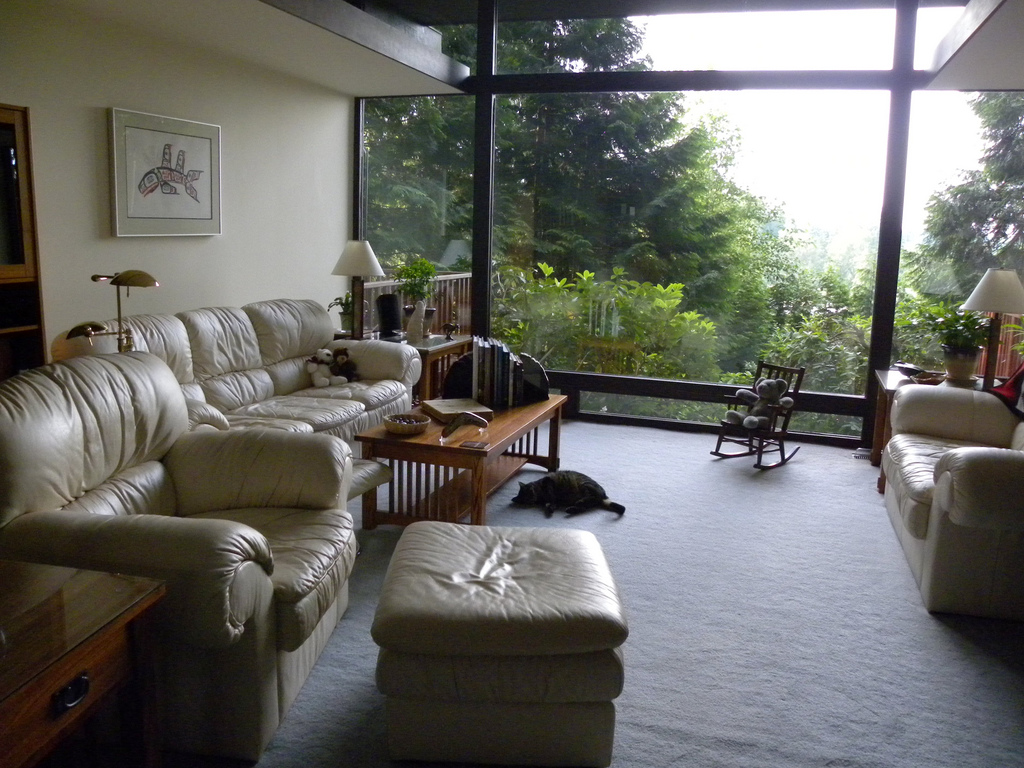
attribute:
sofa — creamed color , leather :
[93, 289, 426, 461]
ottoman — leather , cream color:
[363, 517, 627, 751]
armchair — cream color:
[8, 350, 373, 762]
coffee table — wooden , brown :
[372, 356, 569, 533]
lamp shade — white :
[324, 239, 385, 287]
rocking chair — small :
[720, 361, 796, 475]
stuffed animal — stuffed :
[731, 380, 788, 439]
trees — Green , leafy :
[461, 25, 993, 380]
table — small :
[861, 348, 1007, 412]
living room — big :
[97, 0, 979, 751]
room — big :
[45, 11, 1011, 752]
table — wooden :
[355, 372, 580, 527]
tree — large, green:
[549, 108, 755, 270]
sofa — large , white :
[58, 294, 428, 479]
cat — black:
[503, 449, 627, 527]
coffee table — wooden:
[357, 380, 566, 529]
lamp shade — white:
[329, 237, 384, 339]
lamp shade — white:
[955, 265, 1022, 392]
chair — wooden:
[715, 317, 840, 489]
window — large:
[366, 0, 1022, 441]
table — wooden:
[358, 292, 592, 574]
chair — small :
[700, 358, 809, 472]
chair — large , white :
[8, 342, 365, 749]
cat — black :
[497, 468, 640, 521]